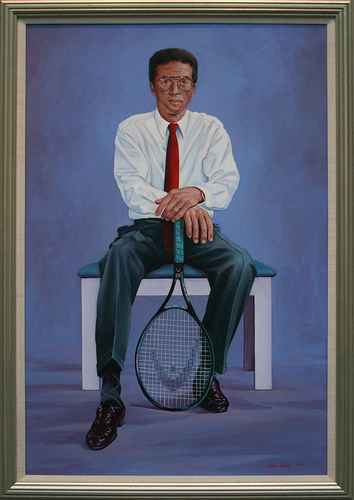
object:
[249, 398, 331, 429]
ground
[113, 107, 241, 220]
shirt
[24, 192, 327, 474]
forefront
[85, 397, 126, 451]
shoe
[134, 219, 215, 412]
racket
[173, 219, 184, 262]
blue handle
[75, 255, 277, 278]
blue cushion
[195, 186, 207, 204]
watch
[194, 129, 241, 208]
shirt sleeve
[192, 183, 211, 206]
wrist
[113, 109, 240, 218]
torso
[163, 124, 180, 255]
tie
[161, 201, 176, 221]
finger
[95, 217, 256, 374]
pants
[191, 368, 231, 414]
shoes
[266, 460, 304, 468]
artist's signature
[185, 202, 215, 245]
hands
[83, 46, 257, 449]
man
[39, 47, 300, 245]
white wall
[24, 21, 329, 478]
painting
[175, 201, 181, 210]
gold ring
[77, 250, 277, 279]
cushion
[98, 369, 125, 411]
socks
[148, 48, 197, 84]
hair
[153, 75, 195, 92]
glasses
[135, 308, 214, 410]
head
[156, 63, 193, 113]
face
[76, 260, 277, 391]
bench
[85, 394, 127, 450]
foot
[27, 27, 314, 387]
background